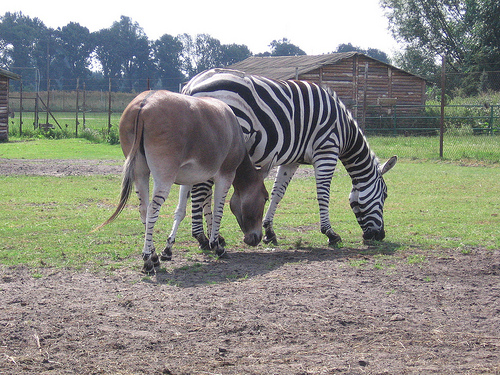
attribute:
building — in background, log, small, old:
[245, 55, 429, 126]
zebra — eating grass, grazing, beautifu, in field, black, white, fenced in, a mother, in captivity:
[190, 64, 398, 248]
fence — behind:
[17, 79, 119, 132]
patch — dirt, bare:
[0, 157, 121, 180]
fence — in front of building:
[358, 102, 497, 136]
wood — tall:
[70, 79, 83, 140]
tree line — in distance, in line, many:
[10, 11, 228, 82]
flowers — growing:
[2, 121, 89, 140]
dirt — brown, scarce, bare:
[27, 268, 499, 373]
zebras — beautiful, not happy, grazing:
[86, 64, 398, 272]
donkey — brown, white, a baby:
[98, 96, 278, 277]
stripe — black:
[146, 192, 159, 261]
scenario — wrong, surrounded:
[2, 1, 500, 367]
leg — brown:
[127, 158, 151, 212]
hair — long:
[97, 149, 150, 228]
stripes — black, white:
[251, 86, 283, 140]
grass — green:
[8, 181, 95, 266]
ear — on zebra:
[377, 152, 400, 173]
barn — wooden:
[282, 49, 459, 136]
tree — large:
[90, 19, 150, 101]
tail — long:
[88, 106, 154, 240]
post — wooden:
[439, 49, 447, 163]